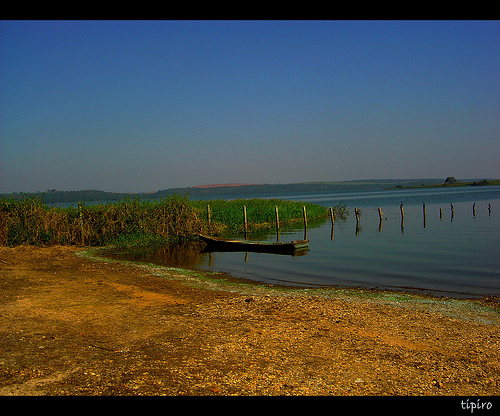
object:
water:
[351, 237, 481, 275]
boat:
[195, 227, 313, 256]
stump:
[371, 206, 393, 232]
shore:
[86, 244, 498, 327]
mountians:
[0, 184, 149, 203]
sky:
[3, 15, 496, 191]